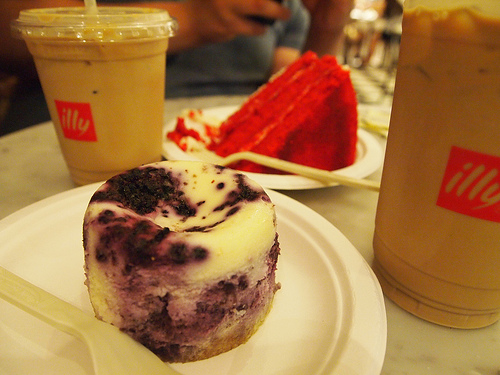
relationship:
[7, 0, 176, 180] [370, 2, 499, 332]
cup with coffee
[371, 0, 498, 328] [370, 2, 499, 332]
cup filled with coffee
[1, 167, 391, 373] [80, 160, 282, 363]
plate with cheesecake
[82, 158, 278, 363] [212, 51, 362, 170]
cake with cake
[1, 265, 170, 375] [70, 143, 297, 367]
fork next to dessert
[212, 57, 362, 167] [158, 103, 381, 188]
cake on plate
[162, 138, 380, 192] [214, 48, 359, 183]
fork next to cake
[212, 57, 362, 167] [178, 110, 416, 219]
cake on plate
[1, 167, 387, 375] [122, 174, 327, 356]
plate with dessert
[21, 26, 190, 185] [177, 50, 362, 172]
coffee on left of cake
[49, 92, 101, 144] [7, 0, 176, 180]
logo on cup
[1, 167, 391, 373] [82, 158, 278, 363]
plate with cake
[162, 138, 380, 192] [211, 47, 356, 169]
fork aside cake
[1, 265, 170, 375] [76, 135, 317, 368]
fork next to dessert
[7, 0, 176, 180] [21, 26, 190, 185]
cup with coffee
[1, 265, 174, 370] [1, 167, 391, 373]
fork on plate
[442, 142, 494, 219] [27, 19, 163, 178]
square logo on plastic cup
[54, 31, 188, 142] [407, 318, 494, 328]
coffee and desserts on table